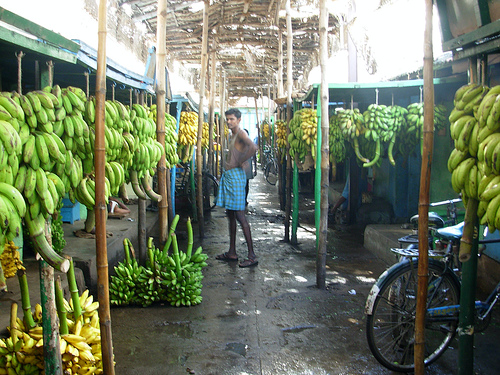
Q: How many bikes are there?
A: 1.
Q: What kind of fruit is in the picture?
A: Bananas.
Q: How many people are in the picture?
A: One.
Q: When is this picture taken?
A: During the daytime.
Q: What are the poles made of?
A: Bamboo.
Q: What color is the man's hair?
A: Black.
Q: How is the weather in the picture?
A: Sunny.